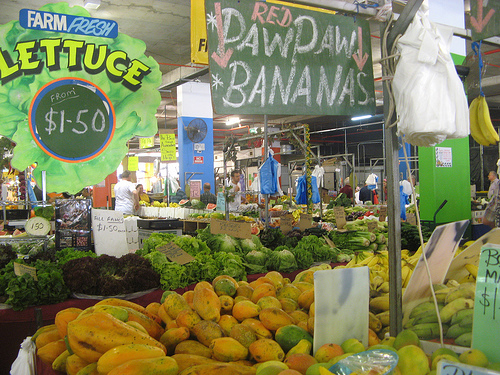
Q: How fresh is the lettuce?
A: Farm Fresh.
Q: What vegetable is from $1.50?
A: Lettuce.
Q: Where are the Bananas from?
A: Paw Paw.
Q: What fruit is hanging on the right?
A: Bananas.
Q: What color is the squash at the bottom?
A: Yellow.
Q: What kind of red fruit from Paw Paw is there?
A: Bananas.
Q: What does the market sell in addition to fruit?
A: Vegetables.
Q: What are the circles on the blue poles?
A: Fans.